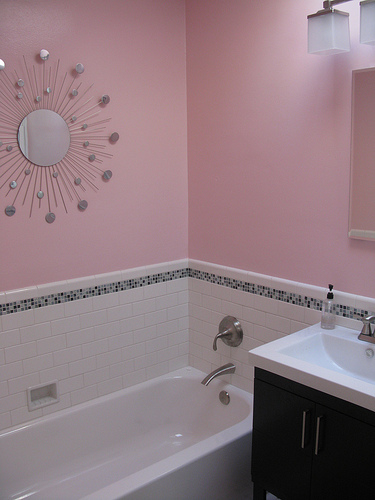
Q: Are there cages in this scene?
A: No, there are no cages.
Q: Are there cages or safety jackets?
A: No, there are no cages or safety jackets.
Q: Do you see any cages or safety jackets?
A: No, there are no cages or safety jackets.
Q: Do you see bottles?
A: Yes, there is a bottle.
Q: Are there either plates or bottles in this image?
A: Yes, there is a bottle.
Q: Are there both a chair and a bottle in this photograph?
A: No, there is a bottle but no chairs.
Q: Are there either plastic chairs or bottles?
A: Yes, there is a plastic bottle.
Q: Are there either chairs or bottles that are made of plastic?
A: Yes, the bottle is made of plastic.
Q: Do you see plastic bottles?
A: Yes, there is a bottle that is made of plastic.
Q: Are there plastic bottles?
A: Yes, there is a bottle that is made of plastic.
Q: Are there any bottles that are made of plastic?
A: Yes, there is a bottle that is made of plastic.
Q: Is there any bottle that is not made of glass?
A: Yes, there is a bottle that is made of plastic.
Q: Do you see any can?
A: No, there are no cans.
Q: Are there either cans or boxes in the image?
A: No, there are no cans or boxes.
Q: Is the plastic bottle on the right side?
A: Yes, the bottle is on the right of the image.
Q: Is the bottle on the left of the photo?
A: No, the bottle is on the right of the image.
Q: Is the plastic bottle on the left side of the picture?
A: No, the bottle is on the right of the image.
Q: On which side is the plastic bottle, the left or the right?
A: The bottle is on the right of the image.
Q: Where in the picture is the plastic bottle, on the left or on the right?
A: The bottle is on the right of the image.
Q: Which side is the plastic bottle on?
A: The bottle is on the right of the image.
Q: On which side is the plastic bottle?
A: The bottle is on the right of the image.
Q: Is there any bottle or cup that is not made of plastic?
A: No, there is a bottle but it is made of plastic.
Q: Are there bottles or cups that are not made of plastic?
A: No, there is a bottle but it is made of plastic.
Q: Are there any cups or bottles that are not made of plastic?
A: No, there is a bottle but it is made of plastic.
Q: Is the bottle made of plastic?
A: Yes, the bottle is made of plastic.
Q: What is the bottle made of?
A: The bottle is made of plastic.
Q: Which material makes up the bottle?
A: The bottle is made of plastic.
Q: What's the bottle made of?
A: The bottle is made of plastic.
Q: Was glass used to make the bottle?
A: No, the bottle is made of plastic.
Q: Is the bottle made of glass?
A: No, the bottle is made of plastic.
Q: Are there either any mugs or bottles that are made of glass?
A: No, there is a bottle but it is made of plastic.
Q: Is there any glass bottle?
A: No, there is a bottle but it is made of plastic.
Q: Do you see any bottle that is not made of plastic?
A: No, there is a bottle but it is made of plastic.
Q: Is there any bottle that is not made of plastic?
A: No, there is a bottle but it is made of plastic.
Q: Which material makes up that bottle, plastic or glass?
A: The bottle is made of plastic.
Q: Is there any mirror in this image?
A: Yes, there is a mirror.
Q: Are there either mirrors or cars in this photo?
A: Yes, there is a mirror.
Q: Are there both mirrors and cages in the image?
A: No, there is a mirror but no cages.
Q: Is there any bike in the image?
A: No, there are no bikes.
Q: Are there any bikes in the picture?
A: No, there are no bikes.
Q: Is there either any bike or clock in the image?
A: No, there are no bikes or clocks.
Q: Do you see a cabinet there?
A: Yes, there is a cabinet.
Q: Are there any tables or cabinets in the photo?
A: Yes, there is a cabinet.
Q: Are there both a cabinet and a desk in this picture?
A: No, there is a cabinet but no desks.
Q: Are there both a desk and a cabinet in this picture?
A: No, there is a cabinet but no desks.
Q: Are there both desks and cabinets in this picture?
A: No, there is a cabinet but no desks.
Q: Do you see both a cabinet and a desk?
A: No, there is a cabinet but no desks.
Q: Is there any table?
A: No, there are no tables.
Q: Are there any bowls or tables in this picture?
A: No, there are no tables or bowls.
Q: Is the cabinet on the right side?
A: Yes, the cabinet is on the right of the image.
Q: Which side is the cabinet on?
A: The cabinet is on the right of the image.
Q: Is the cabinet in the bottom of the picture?
A: Yes, the cabinet is in the bottom of the image.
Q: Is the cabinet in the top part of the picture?
A: No, the cabinet is in the bottom of the image.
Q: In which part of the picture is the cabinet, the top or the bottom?
A: The cabinet is in the bottom of the image.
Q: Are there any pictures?
A: No, there are no pictures.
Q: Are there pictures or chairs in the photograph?
A: No, there are no pictures or chairs.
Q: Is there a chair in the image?
A: No, there are no chairs.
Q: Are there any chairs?
A: No, there are no chairs.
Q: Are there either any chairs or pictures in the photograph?
A: No, there are no chairs or pictures.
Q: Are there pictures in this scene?
A: No, there are no pictures.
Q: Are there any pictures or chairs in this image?
A: No, there are no pictures or chairs.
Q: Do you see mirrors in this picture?
A: Yes, there is a mirror.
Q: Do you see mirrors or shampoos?
A: Yes, there is a mirror.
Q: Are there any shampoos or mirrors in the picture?
A: Yes, there is a mirror.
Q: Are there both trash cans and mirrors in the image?
A: No, there is a mirror but no trash cans.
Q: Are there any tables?
A: No, there are no tables.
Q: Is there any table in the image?
A: No, there are no tables.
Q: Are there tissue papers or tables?
A: No, there are no tables or tissue papers.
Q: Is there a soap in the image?
A: Yes, there is a soap.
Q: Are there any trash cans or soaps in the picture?
A: Yes, there is a soap.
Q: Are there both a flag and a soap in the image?
A: No, there is a soap but no flags.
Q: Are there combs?
A: No, there are no combs.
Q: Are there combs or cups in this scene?
A: No, there are no combs or cups.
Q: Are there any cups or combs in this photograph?
A: No, there are no combs or cups.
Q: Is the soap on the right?
A: Yes, the soap is on the right of the image.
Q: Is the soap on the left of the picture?
A: No, the soap is on the right of the image.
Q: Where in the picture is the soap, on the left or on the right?
A: The soap is on the right of the image.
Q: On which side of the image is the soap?
A: The soap is on the right of the image.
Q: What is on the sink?
A: The soap is on the sink.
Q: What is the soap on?
A: The soap is on the sink.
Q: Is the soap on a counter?
A: No, the soap is on the sink.